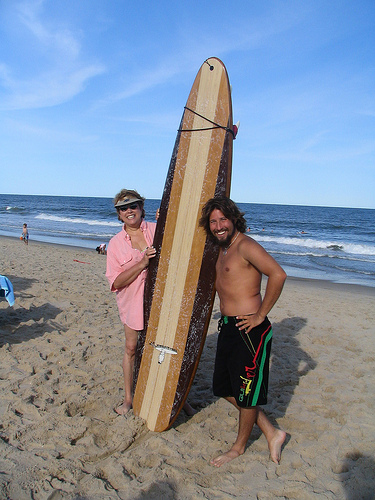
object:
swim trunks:
[211, 313, 279, 413]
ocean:
[268, 207, 368, 252]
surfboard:
[122, 51, 236, 440]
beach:
[0, 192, 373, 496]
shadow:
[0, 302, 68, 348]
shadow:
[165, 331, 221, 430]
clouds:
[1, 4, 134, 185]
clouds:
[264, 39, 352, 94]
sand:
[297, 289, 352, 330]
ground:
[6, 202, 374, 499]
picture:
[0, 2, 374, 497]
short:
[23, 234, 28, 242]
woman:
[100, 170, 170, 417]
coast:
[8, 238, 126, 440]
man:
[190, 184, 294, 474]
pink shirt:
[98, 219, 170, 334]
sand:
[284, 313, 298, 375]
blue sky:
[0, 0, 373, 208]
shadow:
[335, 450, 374, 498]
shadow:
[257, 315, 313, 418]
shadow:
[137, 480, 178, 498]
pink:
[121, 289, 141, 313]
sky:
[0, 0, 375, 207]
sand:
[318, 434, 372, 498]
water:
[285, 188, 354, 277]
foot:
[265, 425, 298, 470]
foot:
[205, 431, 245, 469]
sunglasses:
[118, 199, 139, 213]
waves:
[273, 223, 309, 256]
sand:
[1, 380, 104, 473]